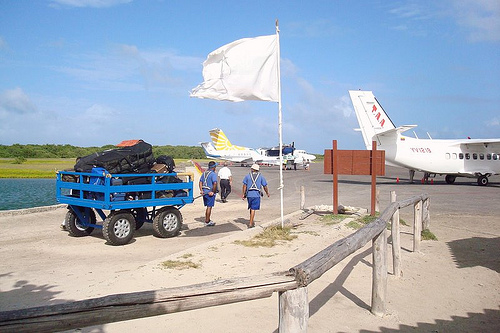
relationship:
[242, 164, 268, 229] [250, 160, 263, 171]
man wearing hat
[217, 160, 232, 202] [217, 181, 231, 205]
man wearing pants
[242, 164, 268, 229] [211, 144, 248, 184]
man wearing shirt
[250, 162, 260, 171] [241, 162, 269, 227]
hat on man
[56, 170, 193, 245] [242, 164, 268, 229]
trailer behind man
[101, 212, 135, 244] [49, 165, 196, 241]
tire on trailer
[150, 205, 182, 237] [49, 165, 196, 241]
tire on trailer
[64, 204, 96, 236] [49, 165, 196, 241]
tire on trailer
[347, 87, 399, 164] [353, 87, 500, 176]
tail of airplane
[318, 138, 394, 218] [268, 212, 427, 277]
sign on ground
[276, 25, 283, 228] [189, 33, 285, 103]
pole with flag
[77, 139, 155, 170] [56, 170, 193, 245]
bags in trailer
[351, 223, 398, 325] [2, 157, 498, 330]
fence post on ground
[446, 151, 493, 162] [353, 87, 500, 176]
windows on airplane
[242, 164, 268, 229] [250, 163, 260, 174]
man in hat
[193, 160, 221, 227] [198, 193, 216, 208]
man in blue shorts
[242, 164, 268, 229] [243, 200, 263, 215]
man in blue shorts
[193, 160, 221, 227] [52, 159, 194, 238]
man pulling wagon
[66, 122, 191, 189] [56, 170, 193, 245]
bags in trailer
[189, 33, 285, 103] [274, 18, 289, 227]
flag on pole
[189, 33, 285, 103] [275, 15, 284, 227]
flag on pole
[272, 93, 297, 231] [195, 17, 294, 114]
pole with flag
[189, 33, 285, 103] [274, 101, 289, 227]
flag on pole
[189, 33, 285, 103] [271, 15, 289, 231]
flag on pole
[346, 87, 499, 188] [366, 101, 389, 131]
airplane with words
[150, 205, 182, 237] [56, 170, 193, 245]
tire on trailer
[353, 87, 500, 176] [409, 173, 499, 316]
airplane on ground